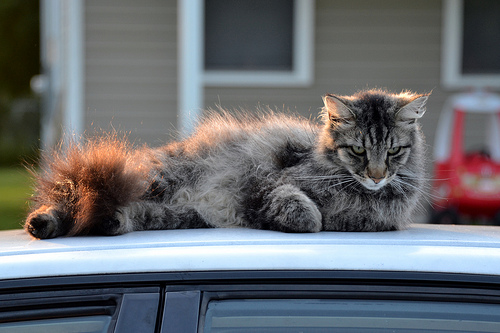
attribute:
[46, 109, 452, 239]
cat — enjoying summer, looking for master, looking for food, staring, gray, black, looking down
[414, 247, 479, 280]
car — blue, white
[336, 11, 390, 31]
house — tan, white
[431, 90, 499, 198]
toy car — red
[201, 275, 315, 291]
window seal — black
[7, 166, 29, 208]
lawn — green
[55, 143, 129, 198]
tail — brown, fluffy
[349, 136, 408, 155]
eyes — green